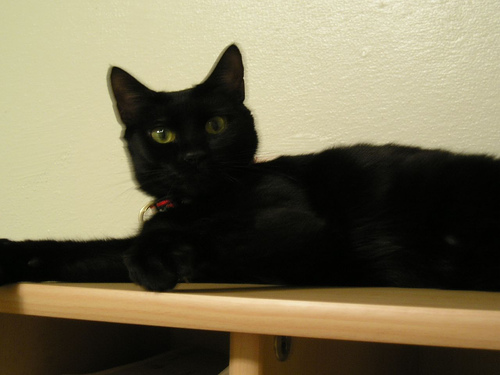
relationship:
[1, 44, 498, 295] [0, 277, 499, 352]
cat on top of shelf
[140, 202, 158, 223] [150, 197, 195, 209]
metal ring attached to collar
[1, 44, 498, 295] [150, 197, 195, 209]
cat wearing collar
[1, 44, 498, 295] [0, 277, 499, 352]
cat lying on shelf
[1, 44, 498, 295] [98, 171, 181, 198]
cat has whiskers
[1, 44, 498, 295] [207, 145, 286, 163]
cat has whiskers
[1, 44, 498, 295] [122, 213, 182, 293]
cat has left paw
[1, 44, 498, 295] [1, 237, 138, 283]
cat has right paw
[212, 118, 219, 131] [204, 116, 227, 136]
pupil inside left eye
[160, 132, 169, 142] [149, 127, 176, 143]
pupil inside right eye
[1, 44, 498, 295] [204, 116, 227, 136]
cat has left eye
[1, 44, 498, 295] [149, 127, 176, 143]
cat has right eye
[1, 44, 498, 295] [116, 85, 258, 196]
cat has head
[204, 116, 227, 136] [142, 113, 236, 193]
left eye in face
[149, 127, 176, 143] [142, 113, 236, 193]
right eye in face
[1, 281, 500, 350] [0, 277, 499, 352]
edge part of shelf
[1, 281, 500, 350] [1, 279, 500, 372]
edge part of table